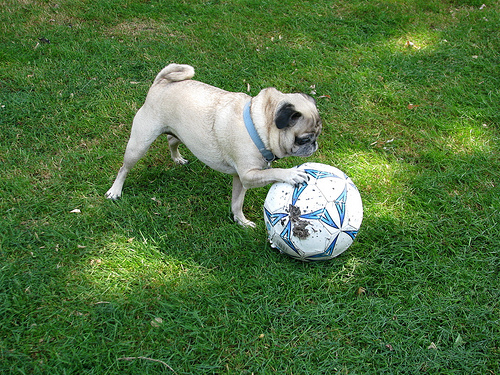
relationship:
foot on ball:
[286, 168, 311, 187] [271, 160, 359, 261]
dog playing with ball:
[87, 52, 326, 178] [271, 160, 359, 261]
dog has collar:
[87, 52, 326, 178] [237, 91, 271, 154]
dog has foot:
[87, 52, 326, 178] [286, 168, 311, 187]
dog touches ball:
[87, 52, 326, 178] [271, 160, 359, 261]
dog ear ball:
[87, 52, 326, 178] [271, 160, 359, 261]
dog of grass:
[87, 52, 326, 178] [353, 44, 385, 97]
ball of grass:
[271, 160, 359, 261] [353, 44, 385, 97]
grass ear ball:
[353, 44, 385, 97] [271, 160, 359, 261]